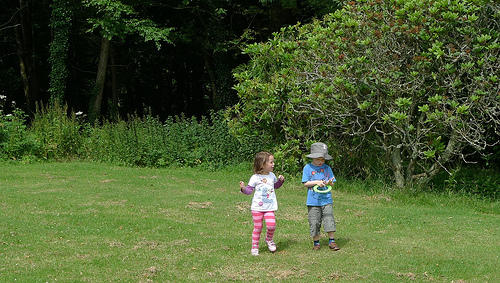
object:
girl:
[239, 151, 286, 256]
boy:
[301, 142, 341, 251]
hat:
[305, 142, 334, 161]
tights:
[251, 210, 277, 249]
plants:
[121, 102, 166, 169]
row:
[0, 100, 272, 170]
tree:
[228, 0, 499, 190]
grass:
[0, 162, 500, 283]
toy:
[313, 183, 333, 194]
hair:
[252, 150, 274, 174]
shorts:
[307, 203, 337, 237]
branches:
[347, 118, 380, 136]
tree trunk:
[49, 1, 70, 113]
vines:
[47, 0, 70, 106]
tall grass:
[334, 172, 499, 213]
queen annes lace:
[0, 94, 26, 118]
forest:
[1, 0, 340, 126]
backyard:
[0, 0, 497, 282]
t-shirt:
[301, 163, 338, 207]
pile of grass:
[186, 199, 214, 211]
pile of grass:
[232, 199, 251, 214]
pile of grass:
[203, 261, 311, 280]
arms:
[241, 174, 256, 195]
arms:
[274, 173, 284, 189]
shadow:
[258, 238, 299, 253]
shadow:
[312, 235, 351, 251]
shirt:
[240, 171, 285, 212]